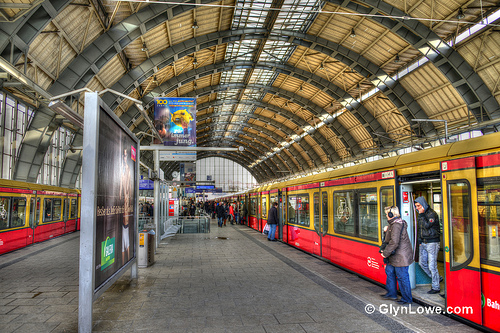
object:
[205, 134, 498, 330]
train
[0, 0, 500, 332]
train station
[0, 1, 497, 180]
domed ceiling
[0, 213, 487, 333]
floor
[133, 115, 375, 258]
center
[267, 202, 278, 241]
person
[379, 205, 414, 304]
people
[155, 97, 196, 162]
sign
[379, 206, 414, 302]
person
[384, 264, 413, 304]
blue pants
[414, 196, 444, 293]
man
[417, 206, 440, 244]
black jacket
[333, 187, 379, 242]
windows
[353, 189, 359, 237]
black trimming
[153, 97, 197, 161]
billboards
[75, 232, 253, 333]
alongside  train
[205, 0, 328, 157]
windows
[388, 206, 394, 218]
headphones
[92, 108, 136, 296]
sign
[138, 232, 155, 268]
trash can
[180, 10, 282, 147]
lights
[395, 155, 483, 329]
off train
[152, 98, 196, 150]
movie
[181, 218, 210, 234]
stairs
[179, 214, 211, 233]
lower level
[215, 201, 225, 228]
people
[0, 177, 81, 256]
train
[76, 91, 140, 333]
platform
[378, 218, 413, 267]
jacket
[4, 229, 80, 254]
tracks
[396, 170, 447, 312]
door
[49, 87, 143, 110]
lights